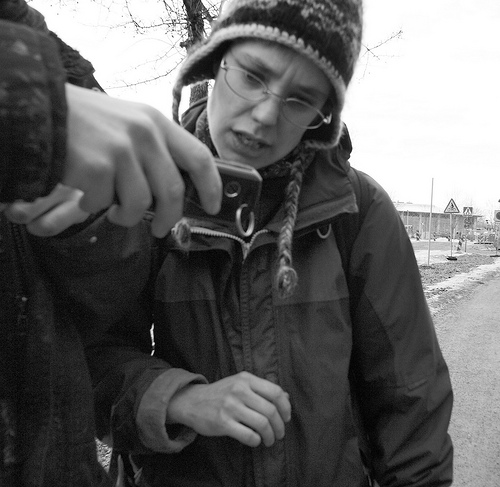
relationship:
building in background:
[404, 189, 486, 242] [407, 141, 468, 185]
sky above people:
[405, 22, 498, 126] [3, 2, 473, 483]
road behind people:
[454, 296, 495, 364] [3, 2, 473, 483]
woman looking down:
[165, 3, 379, 183] [211, 47, 353, 134]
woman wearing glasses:
[165, 3, 379, 183] [217, 57, 330, 134]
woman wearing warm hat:
[165, 3, 379, 183] [189, 3, 374, 59]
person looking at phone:
[164, 5, 367, 116] [223, 157, 264, 241]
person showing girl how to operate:
[2, 4, 131, 464] [237, 177, 252, 196]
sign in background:
[439, 194, 461, 217] [407, 141, 468, 185]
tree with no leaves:
[81, 0, 192, 78] [157, 17, 162, 21]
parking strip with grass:
[434, 277, 477, 298] [445, 262, 459, 275]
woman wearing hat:
[165, 3, 379, 183] [189, 3, 374, 59]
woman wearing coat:
[165, 3, 379, 183] [186, 219, 492, 463]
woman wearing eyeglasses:
[165, 3, 379, 183] [217, 57, 330, 134]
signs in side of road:
[441, 194, 479, 221] [454, 296, 495, 364]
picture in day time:
[6, 5, 484, 478] [407, 53, 447, 86]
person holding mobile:
[2, 4, 131, 464] [223, 157, 264, 241]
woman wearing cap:
[165, 3, 379, 183] [189, 3, 374, 59]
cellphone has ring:
[223, 157, 264, 241] [234, 199, 259, 238]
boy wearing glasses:
[165, 3, 379, 183] [217, 57, 330, 134]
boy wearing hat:
[165, 3, 379, 183] [189, 3, 374, 59]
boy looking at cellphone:
[165, 3, 379, 183] [223, 157, 264, 241]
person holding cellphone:
[2, 4, 131, 464] [223, 157, 264, 241]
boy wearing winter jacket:
[165, 3, 379, 183] [273, 188, 450, 470]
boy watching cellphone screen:
[165, 3, 379, 183] [223, 157, 264, 241]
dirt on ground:
[445, 290, 464, 298] [470, 305, 495, 350]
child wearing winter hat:
[165, 3, 379, 183] [189, 3, 374, 59]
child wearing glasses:
[165, 3, 379, 183] [217, 57, 330, 134]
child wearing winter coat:
[165, 3, 379, 183] [273, 188, 450, 470]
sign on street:
[439, 194, 461, 217] [461, 312, 488, 345]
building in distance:
[404, 189, 486, 242] [457, 126, 470, 139]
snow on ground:
[455, 277, 464, 286] [470, 305, 495, 350]